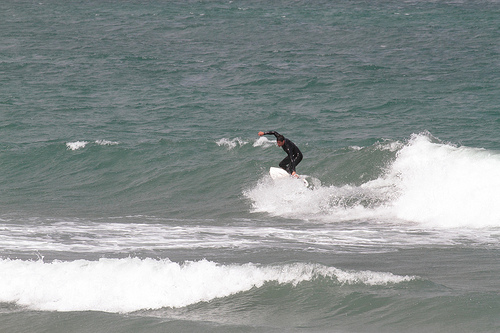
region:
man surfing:
[248, 113, 309, 180]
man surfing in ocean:
[250, 124, 310, 183]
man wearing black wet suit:
[258, 120, 306, 170]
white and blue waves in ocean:
[1, 212, 237, 322]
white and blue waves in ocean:
[212, 187, 485, 307]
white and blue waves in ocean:
[311, 3, 497, 248]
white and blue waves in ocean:
[147, 10, 381, 125]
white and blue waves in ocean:
[7, 6, 178, 218]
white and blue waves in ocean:
[122, 5, 247, 225]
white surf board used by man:
[266, 165, 289, 185]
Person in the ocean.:
[238, 107, 327, 224]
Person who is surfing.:
[239, 102, 354, 211]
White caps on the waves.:
[250, 147, 356, 237]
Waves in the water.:
[60, 127, 337, 237]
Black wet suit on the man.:
[254, 112, 339, 200]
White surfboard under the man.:
[240, 112, 347, 211]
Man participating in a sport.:
[252, 115, 335, 212]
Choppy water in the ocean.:
[57, 195, 342, 331]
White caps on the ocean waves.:
[189, 22, 437, 258]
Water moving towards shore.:
[28, 275, 295, 330]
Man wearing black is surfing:
[238, 113, 318, 181]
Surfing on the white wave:
[245, 166, 436, 232]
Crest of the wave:
[22, 131, 498, 172]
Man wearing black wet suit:
[278, 154, 301, 169]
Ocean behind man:
[18, 12, 495, 117]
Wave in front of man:
[25, 252, 498, 307]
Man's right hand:
[256, 127, 264, 139]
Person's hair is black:
[275, 131, 284, 152]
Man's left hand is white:
[286, 170, 298, 177]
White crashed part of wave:
[393, 122, 489, 242]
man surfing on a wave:
[245, 116, 331, 216]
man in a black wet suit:
[239, 106, 320, 196]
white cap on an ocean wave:
[394, 128, 466, 233]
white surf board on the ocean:
[265, 165, 310, 202]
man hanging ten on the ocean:
[231, 96, 344, 226]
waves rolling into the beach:
[45, 236, 328, 316]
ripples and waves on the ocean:
[136, 39, 238, 91]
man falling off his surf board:
[231, 121, 345, 213]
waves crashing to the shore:
[102, 244, 392, 312]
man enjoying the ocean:
[211, 89, 373, 220]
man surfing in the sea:
[248, 120, 308, 192]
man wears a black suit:
[256, 120, 311, 196]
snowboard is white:
[259, 157, 303, 199]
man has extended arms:
[244, 119, 316, 187]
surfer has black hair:
[233, 114, 313, 191]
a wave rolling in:
[320, 117, 496, 235]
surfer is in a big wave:
[9, 116, 494, 241]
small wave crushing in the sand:
[6, 246, 390, 316]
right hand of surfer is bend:
[251, 119, 288, 151]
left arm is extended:
[284, 144, 305, 185]